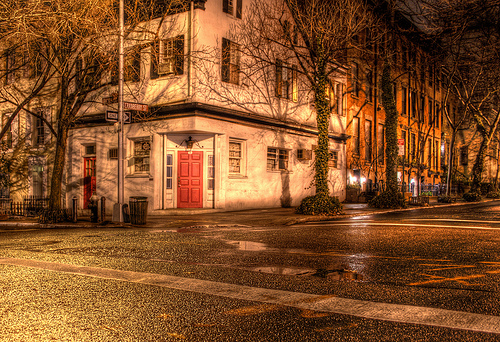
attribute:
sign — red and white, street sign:
[384, 133, 419, 170]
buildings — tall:
[0, 0, 498, 219]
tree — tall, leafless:
[16, 15, 109, 215]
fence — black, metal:
[10, 187, 90, 221]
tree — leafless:
[226, 1, 395, 193]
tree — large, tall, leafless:
[225, 0, 387, 218]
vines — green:
[296, 79, 344, 214]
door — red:
[170, 146, 208, 208]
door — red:
[80, 154, 99, 212]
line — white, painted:
[11, 247, 498, 338]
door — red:
[177, 150, 204, 207]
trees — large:
[11, 0, 193, 168]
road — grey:
[82, 236, 485, 314]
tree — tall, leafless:
[283, 10, 360, 205]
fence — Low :
[3, 192, 54, 220]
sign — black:
[103, 107, 130, 123]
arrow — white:
[107, 112, 129, 121]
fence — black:
[11, 195, 72, 215]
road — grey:
[1, 197, 499, 340]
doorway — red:
[175, 147, 205, 210]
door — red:
[83, 152, 95, 209]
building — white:
[63, 0, 348, 214]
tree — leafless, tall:
[258, 17, 499, 229]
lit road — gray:
[47, 222, 372, 332]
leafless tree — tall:
[344, 3, 441, 224]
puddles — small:
[36, 232, 116, 254]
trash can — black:
[125, 192, 155, 244]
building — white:
[90, 21, 334, 200]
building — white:
[75, 13, 338, 204]